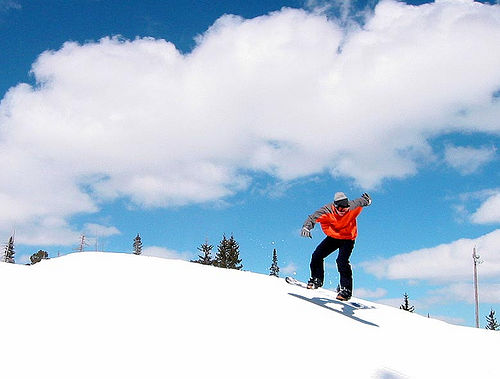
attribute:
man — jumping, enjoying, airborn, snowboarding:
[300, 189, 371, 301]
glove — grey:
[299, 226, 314, 240]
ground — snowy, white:
[0, 252, 499, 376]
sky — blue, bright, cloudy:
[1, 1, 499, 328]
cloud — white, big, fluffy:
[2, 0, 499, 246]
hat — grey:
[333, 189, 346, 200]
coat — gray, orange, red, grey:
[303, 196, 368, 241]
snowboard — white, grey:
[285, 275, 369, 311]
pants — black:
[309, 235, 354, 292]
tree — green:
[28, 247, 49, 264]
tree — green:
[132, 232, 144, 257]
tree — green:
[190, 239, 218, 267]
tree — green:
[217, 231, 245, 270]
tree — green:
[269, 248, 280, 278]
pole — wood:
[472, 246, 481, 328]